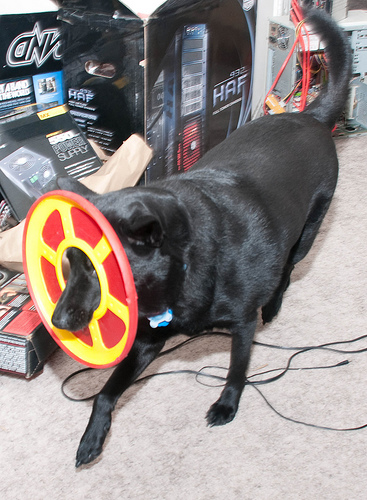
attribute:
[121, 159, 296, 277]
dog — black, standing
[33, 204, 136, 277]
frisbee — red, round, yellow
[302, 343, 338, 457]
wire — black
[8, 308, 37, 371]
box — square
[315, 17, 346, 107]
tail — long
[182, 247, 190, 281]
collar — blue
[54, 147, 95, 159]
letters — white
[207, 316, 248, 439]
leg — black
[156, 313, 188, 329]
tag — blue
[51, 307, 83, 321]
nose — black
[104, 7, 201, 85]
box — black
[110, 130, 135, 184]
bag — brown, paper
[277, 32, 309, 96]
wires — orange, hanging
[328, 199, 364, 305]
carpet — tan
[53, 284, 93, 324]
snout — black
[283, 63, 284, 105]
cord — orange